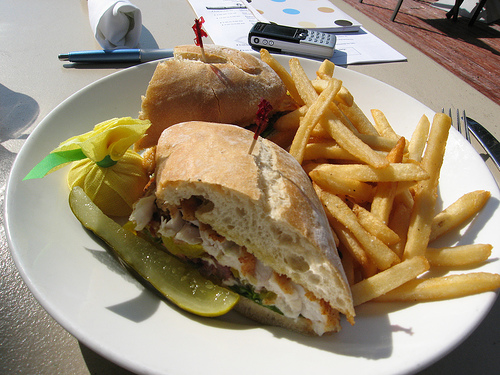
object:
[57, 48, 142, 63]
blue pen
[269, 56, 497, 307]
french fries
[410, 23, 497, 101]
ground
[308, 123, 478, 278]
fries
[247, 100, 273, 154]
tooth pick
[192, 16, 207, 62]
tooth pick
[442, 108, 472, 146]
fork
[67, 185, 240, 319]
pickle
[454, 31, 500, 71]
floor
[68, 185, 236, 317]
cocktail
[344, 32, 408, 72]
paper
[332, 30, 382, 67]
paper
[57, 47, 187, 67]
pen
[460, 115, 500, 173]
knife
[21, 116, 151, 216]
sack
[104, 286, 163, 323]
shadow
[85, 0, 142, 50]
napkin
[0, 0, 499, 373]
desk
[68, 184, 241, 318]
green pickle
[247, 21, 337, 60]
cell phone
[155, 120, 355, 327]
bread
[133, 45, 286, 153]
bread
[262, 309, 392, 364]
shadow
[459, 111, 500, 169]
knife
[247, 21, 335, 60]
mobile phone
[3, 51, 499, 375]
plate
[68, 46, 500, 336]
food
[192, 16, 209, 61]
plastic top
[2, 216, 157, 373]
plate edge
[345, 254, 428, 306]
fry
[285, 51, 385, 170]
fry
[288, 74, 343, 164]
fry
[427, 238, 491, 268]
fry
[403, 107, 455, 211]
fry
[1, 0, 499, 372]
table